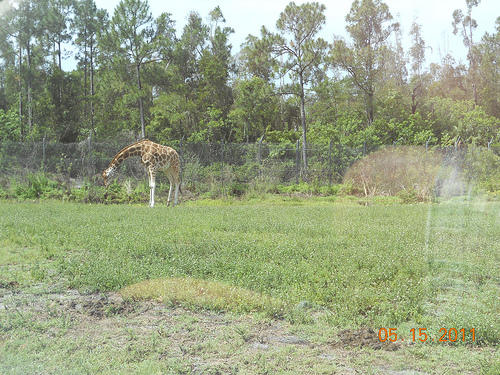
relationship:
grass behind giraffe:
[1, 171, 499, 202] [100, 135, 192, 206]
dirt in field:
[10, 286, 348, 363] [1, 173, 498, 373]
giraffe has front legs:
[100, 135, 192, 206] [143, 165, 158, 207]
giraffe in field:
[100, 135, 192, 206] [1, 173, 498, 373]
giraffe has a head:
[100, 135, 192, 206] [100, 163, 120, 187]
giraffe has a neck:
[100, 135, 192, 206] [108, 140, 141, 168]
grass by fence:
[1, 171, 499, 202] [2, 138, 500, 201]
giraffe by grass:
[100, 135, 192, 206] [1, 171, 499, 202]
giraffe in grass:
[100, 135, 192, 206] [1, 191, 499, 372]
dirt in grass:
[10, 286, 348, 363] [1, 191, 499, 372]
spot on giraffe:
[130, 146, 139, 154] [100, 135, 192, 206]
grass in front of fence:
[1, 171, 499, 202] [2, 138, 500, 201]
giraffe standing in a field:
[100, 135, 192, 206] [1, 173, 498, 373]